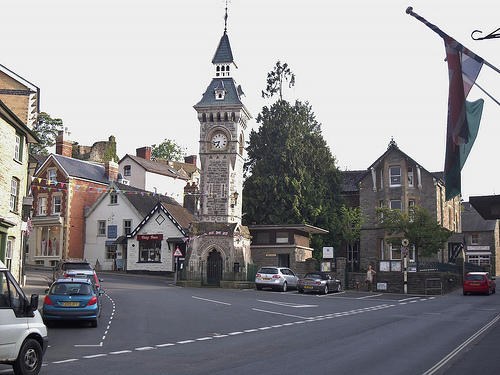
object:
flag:
[402, 3, 499, 203]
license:
[58, 300, 80, 307]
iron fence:
[187, 258, 248, 287]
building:
[347, 133, 466, 296]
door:
[200, 242, 226, 290]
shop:
[119, 200, 193, 277]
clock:
[206, 130, 234, 153]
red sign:
[135, 232, 165, 243]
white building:
[79, 177, 142, 271]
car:
[294, 264, 344, 295]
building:
[26, 151, 131, 271]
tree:
[245, 61, 354, 274]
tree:
[321, 199, 374, 278]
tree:
[377, 205, 456, 271]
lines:
[246, 304, 309, 322]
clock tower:
[176, 0, 256, 290]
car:
[40, 277, 105, 327]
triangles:
[126, 191, 187, 240]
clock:
[203, 125, 235, 152]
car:
[253, 263, 290, 292]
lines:
[188, 293, 235, 308]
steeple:
[187, 0, 248, 113]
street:
[21, 268, 500, 375]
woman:
[363, 260, 377, 293]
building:
[0, 99, 46, 288]